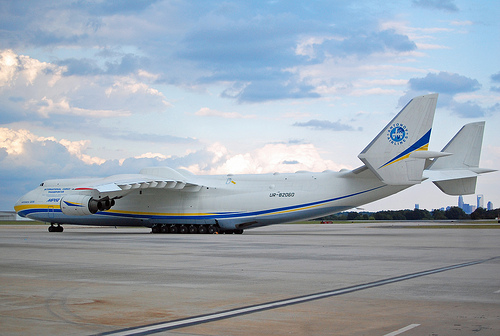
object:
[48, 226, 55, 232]
wheel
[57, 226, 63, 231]
wheel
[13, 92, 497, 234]
airplane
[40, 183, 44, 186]
window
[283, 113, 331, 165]
ground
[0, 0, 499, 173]
cloud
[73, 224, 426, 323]
roadway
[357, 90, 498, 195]
tail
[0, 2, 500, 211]
sky